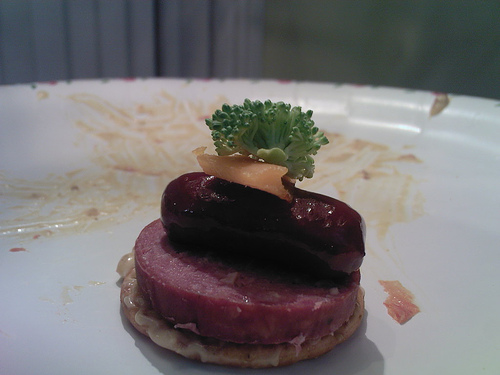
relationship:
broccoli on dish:
[202, 97, 331, 184] [0, 77, 499, 373]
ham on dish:
[158, 171, 365, 278] [0, 77, 499, 373]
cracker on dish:
[118, 252, 366, 367] [0, 77, 499, 373]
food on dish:
[117, 97, 370, 374] [0, 77, 499, 373]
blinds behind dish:
[3, 0, 267, 100] [0, 77, 499, 373]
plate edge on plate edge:
[0, 75, 499, 108] [0, 75, 499, 108]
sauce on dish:
[375, 277, 417, 325] [0, 77, 499, 373]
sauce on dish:
[0, 93, 429, 244] [0, 77, 499, 373]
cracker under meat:
[118, 252, 366, 367] [130, 212, 363, 350]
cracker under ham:
[118, 252, 366, 367] [158, 171, 365, 278]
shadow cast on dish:
[119, 313, 385, 373] [7, 77, 494, 373]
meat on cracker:
[135, 217, 362, 341] [118, 252, 366, 367]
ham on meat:
[158, 171, 365, 278] [135, 217, 362, 341]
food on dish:
[117, 97, 370, 374] [7, 77, 494, 373]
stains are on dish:
[5, 68, 206, 271] [7, 77, 494, 373]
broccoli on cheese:
[202, 97, 331, 184] [199, 156, 297, 203]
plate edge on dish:
[0, 75, 499, 108] [0, 77, 499, 373]